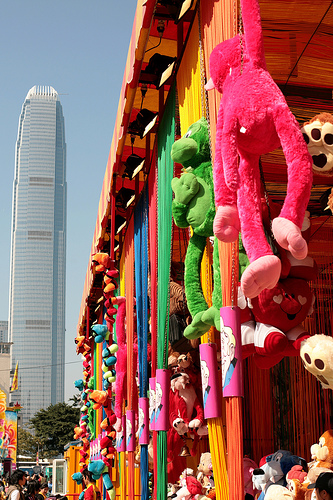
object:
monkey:
[203, 0, 314, 299]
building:
[7, 85, 66, 437]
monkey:
[169, 117, 252, 340]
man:
[6, 470, 27, 499]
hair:
[9, 469, 27, 484]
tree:
[28, 401, 82, 458]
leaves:
[59, 410, 65, 422]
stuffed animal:
[238, 276, 319, 369]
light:
[127, 107, 160, 141]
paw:
[298, 110, 332, 172]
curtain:
[156, 83, 176, 500]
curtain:
[199, 0, 241, 499]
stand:
[167, 430, 332, 499]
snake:
[90, 252, 120, 470]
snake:
[91, 323, 119, 391]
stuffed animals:
[289, 428, 332, 500]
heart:
[202, 33, 240, 94]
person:
[307, 469, 333, 499]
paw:
[170, 171, 200, 205]